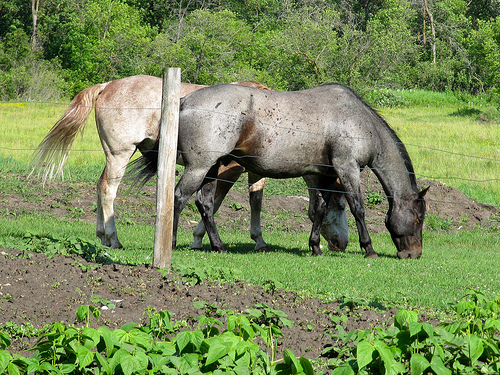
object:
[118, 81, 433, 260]
horse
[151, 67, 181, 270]
post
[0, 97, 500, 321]
grass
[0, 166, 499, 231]
dirt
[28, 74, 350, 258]
horse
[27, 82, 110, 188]
tail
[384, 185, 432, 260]
head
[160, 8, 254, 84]
tree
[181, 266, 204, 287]
plant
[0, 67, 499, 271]
fence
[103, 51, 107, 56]
leaf